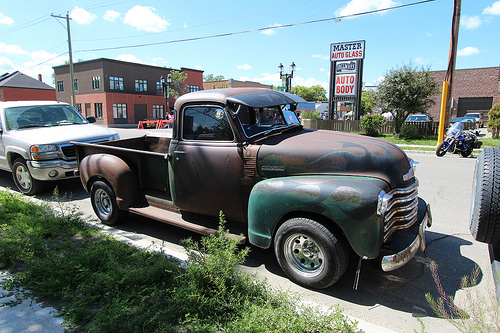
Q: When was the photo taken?
A: During the daytime.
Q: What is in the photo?
A: A car.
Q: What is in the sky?
A: Clouds.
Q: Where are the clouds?
A: In the sky.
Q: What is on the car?
A: A wheel.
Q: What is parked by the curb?
A: A truck.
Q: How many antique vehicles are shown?
A: One.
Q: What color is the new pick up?
A: White.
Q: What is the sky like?
A: Mostly sunny.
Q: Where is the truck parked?
A: On the street.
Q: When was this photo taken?
A: During the day.